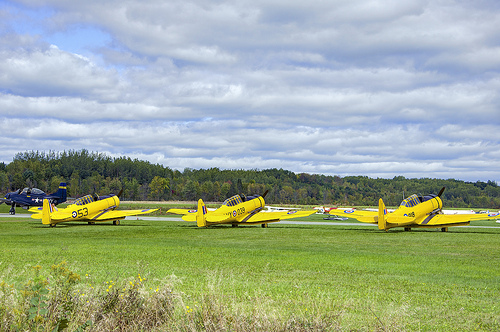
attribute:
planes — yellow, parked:
[27, 161, 445, 251]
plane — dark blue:
[18, 171, 88, 236]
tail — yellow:
[185, 193, 236, 258]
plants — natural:
[18, 268, 183, 329]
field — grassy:
[50, 216, 371, 327]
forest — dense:
[45, 155, 269, 215]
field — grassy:
[72, 226, 379, 324]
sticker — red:
[308, 204, 357, 206]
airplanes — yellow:
[43, 140, 491, 292]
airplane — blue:
[7, 184, 68, 213]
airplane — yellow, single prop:
[24, 190, 158, 228]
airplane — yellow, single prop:
[165, 188, 319, 233]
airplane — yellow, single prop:
[318, 184, 499, 235]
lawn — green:
[12, 219, 485, 290]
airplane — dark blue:
[4, 178, 73, 215]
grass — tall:
[6, 261, 466, 330]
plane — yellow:
[168, 182, 319, 230]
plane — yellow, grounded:
[318, 180, 494, 235]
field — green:
[54, 221, 478, 309]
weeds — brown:
[70, 280, 242, 330]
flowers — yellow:
[23, 252, 78, 297]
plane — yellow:
[27, 184, 159, 228]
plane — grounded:
[6, 178, 72, 216]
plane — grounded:
[26, 181, 156, 229]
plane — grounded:
[168, 187, 321, 230]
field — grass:
[10, 215, 490, 295]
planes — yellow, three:
[22, 175, 493, 235]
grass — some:
[72, 229, 350, 251]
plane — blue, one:
[9, 172, 54, 208]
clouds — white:
[71, 40, 335, 150]